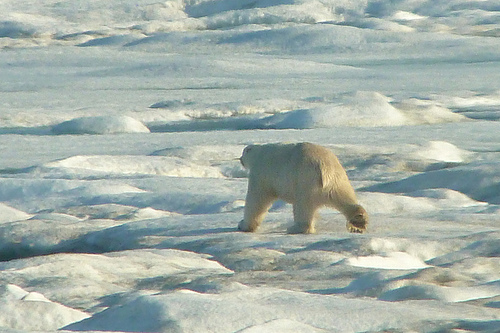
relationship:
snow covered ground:
[382, 152, 462, 239] [89, 74, 456, 285]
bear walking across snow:
[228, 125, 385, 247] [192, 22, 378, 114]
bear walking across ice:
[237, 142, 368, 235] [0, 1, 492, 331]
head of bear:
[237, 146, 257, 168] [234, 141, 372, 238]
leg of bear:
[238, 185, 272, 233] [234, 141, 372, 238]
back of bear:
[253, 133, 340, 155] [230, 136, 374, 241]